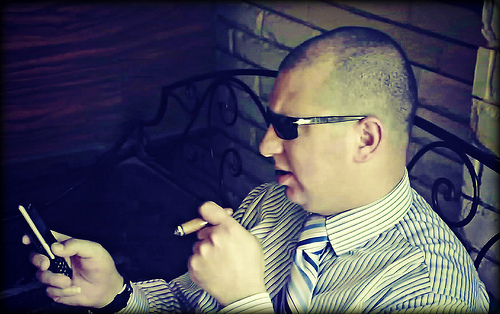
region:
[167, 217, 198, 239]
a cigar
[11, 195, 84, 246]
the man is holding a phone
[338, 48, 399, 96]
the man has low hair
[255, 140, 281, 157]
the nose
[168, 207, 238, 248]
the man is holding a cigar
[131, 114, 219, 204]
a bench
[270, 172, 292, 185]
bottom lip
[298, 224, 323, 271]
the tie is stripped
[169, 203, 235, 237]
a cigar nice and short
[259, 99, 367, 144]
a pair of shades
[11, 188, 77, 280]
phone being used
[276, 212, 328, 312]
a striped tie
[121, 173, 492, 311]
a striped shirt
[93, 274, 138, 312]
a watch on wrist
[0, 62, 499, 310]
wrought iron bench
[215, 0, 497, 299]
a building behind bench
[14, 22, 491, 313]
a man sitting down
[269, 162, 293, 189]
mouth is open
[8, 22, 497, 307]
A MAN SITTING ON A METAL BENCH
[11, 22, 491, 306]
A MAN SMOKING A CIGAR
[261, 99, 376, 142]
A PAIR OF SUNGLASSES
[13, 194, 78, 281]
A BLACK CELLPHONE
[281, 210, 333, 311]
A STRIPED TIE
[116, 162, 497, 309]
A MANS STRIPED SHIRT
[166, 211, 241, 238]
A LIT CIGAR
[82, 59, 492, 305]
A BLACK METAL BENCH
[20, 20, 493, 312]
A MAN WEARING A STRIPED SHIRT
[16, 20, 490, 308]
A PHOTO OF A MAN WEARING A TIE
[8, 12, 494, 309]
Man holding a cigar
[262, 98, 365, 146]
Sunglasses on the man's face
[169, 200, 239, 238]
Cigar in the man's hand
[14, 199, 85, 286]
Cell phone in the man's hand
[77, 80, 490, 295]
Metal bench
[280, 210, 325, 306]
Striped tie on the man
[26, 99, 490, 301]
The man is sitting on a bench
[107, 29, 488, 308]
Man in a shirt and tie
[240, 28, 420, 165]
The man's head is shaved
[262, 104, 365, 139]
sunglasses on a man's face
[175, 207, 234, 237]
a cigar in a man's hand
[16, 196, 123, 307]
cellphone in a man's hand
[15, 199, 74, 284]
a black phone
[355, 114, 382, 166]
man has an ear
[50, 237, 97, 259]
thumb of a man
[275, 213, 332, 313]
a tie around a man's neck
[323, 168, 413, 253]
collar on a man's shirt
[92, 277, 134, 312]
watch on a man's wrist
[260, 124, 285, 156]
nose of a man